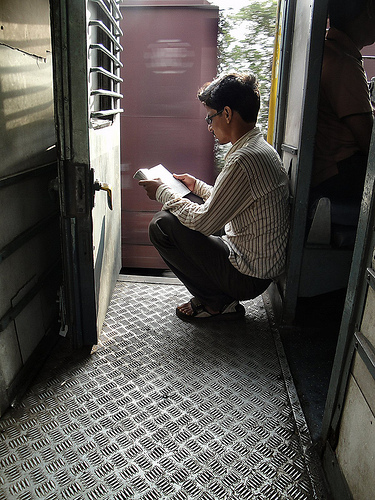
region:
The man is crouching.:
[118, 66, 308, 325]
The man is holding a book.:
[126, 149, 197, 209]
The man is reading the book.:
[125, 60, 298, 327]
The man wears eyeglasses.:
[199, 107, 229, 126]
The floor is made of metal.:
[56, 354, 294, 498]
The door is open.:
[58, 0, 146, 363]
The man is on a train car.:
[3, 2, 371, 497]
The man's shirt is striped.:
[168, 126, 301, 284]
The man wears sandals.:
[164, 290, 256, 329]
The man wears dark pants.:
[143, 203, 279, 304]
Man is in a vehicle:
[133, 60, 297, 339]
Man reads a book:
[130, 65, 301, 347]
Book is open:
[132, 155, 194, 211]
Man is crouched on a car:
[129, 64, 306, 343]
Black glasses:
[200, 109, 222, 128]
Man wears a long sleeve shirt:
[138, 63, 314, 357]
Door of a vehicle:
[19, 0, 136, 356]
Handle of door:
[94, 177, 121, 216]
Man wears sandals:
[138, 63, 308, 339]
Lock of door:
[43, 159, 120, 223]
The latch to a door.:
[92, 177, 114, 213]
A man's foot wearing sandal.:
[166, 295, 244, 322]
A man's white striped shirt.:
[227, 153, 282, 266]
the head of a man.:
[193, 69, 249, 143]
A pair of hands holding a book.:
[136, 159, 201, 212]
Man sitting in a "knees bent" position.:
[133, 71, 287, 314]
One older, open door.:
[54, 0, 132, 342]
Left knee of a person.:
[146, 208, 194, 268]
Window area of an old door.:
[78, 1, 120, 123]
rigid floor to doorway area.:
[101, 320, 290, 452]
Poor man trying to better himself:
[123, 55, 304, 351]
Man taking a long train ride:
[117, 59, 300, 385]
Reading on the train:
[107, 43, 314, 383]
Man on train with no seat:
[112, 37, 313, 347]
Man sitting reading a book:
[122, 57, 298, 372]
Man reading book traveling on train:
[142, 62, 309, 319]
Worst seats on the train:
[69, 15, 340, 476]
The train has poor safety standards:
[86, 21, 326, 431]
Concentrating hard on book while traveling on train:
[87, 34, 323, 405]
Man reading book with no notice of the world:
[93, 55, 328, 395]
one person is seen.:
[33, 31, 301, 312]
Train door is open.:
[75, 1, 322, 364]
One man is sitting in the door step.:
[141, 77, 276, 294]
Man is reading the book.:
[135, 147, 196, 212]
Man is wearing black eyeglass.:
[196, 96, 236, 141]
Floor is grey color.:
[97, 390, 191, 480]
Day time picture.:
[6, 9, 328, 313]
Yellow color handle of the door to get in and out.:
[262, 7, 286, 160]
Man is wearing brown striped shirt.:
[210, 180, 273, 262]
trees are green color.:
[223, 29, 265, 75]